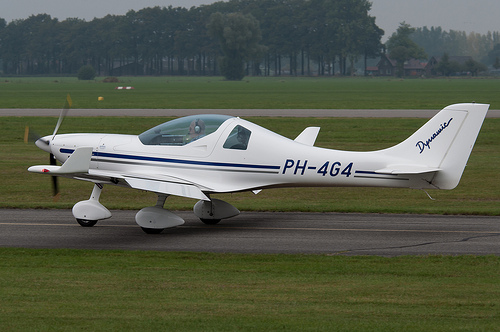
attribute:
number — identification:
[281, 155, 355, 182]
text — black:
[416, 115, 454, 155]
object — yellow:
[96, 94, 105, 103]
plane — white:
[25, 94, 492, 233]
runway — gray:
[2, 205, 484, 257]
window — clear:
[138, 112, 233, 144]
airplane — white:
[23, 85, 480, 278]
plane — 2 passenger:
[14, 98, 497, 258]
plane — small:
[18, 59, 497, 251]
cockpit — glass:
[111, 92, 264, 174]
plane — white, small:
[22, 76, 498, 255]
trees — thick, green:
[2, 0, 497, 99]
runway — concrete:
[14, 193, 497, 262]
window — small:
[218, 116, 257, 172]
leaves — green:
[280, 15, 345, 40]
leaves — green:
[116, 26, 236, 47]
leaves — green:
[34, 18, 133, 79]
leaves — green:
[114, 10, 256, 53]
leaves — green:
[217, 0, 327, 88]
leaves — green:
[389, 29, 424, 59]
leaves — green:
[32, 22, 106, 82]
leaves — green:
[74, 23, 154, 77]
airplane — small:
[11, 52, 498, 248]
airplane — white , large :
[23, 99, 488, 234]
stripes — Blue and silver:
[61, 146, 429, 182]